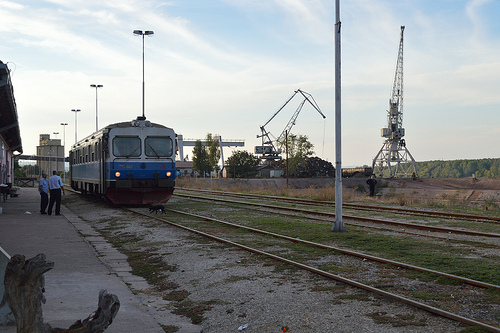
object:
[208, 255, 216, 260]
mark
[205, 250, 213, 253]
mark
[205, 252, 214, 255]
mark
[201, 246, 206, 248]
mark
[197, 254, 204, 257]
mark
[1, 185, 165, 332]
sidewalk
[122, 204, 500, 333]
railroad tracks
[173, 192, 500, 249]
railroad tracks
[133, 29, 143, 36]
light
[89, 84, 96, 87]
light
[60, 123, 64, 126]
light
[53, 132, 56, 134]
light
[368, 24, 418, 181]
crane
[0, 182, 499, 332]
ground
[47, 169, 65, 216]
men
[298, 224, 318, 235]
moss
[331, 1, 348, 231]
pole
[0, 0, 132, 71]
clouds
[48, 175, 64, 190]
shirt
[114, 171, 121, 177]
train headlights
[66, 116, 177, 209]
train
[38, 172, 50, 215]
men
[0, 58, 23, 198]
building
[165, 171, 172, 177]
train lights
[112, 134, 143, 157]
windows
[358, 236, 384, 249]
grass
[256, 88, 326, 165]
construction equipment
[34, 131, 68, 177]
building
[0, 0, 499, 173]
sky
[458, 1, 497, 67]
cloud